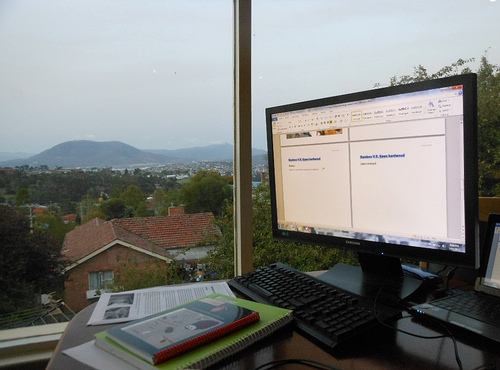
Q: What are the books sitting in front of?
A: A computer.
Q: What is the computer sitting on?
A: A desk.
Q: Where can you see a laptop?
A: Behind the big screened computer.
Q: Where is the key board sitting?
A: On desk infront of computer.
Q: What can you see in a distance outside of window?
A: A big hill.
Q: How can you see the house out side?
A: You can see it from the window.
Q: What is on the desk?
A: A notepad.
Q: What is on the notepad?
A: A book.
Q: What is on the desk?
A: A computer screen.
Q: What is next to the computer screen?
A: A keyboard.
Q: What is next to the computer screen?
A: A window.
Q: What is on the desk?
A: A document.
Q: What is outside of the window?
A: A house.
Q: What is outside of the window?
A: Trees.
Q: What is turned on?
A: A computer screen.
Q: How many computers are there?
A: Two.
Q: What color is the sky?
A: Light blue.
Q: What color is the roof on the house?
A: Red.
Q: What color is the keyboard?
A: Black.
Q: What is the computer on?
A: A desk.